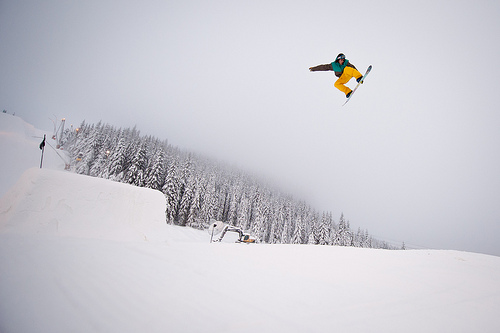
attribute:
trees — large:
[59, 120, 405, 249]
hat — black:
[334, 48, 346, 60]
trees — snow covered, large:
[56, 115, 408, 259]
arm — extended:
[310, 62, 332, 72]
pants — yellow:
[327, 65, 368, 99]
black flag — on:
[39, 133, 48, 149]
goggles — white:
[336, 53, 344, 59]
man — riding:
[302, 49, 374, 109]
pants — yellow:
[337, 67, 367, 96]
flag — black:
[36, 131, 48, 148]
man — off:
[301, 44, 381, 119]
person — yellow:
[278, 33, 388, 120]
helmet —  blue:
[333, 52, 347, 59]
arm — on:
[300, 61, 332, 74]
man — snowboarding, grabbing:
[307, 52, 363, 97]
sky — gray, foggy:
[383, 97, 452, 209]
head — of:
[335, 53, 344, 67]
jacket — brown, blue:
[328, 58, 363, 95]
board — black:
[338, 64, 373, 109]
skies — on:
[309, 49, 372, 99]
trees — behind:
[91, 125, 399, 248]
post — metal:
[40, 134, 45, 169]